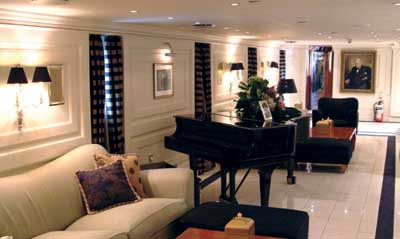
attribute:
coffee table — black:
[179, 202, 307, 236]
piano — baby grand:
[165, 101, 304, 205]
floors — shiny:
[191, 134, 389, 237]